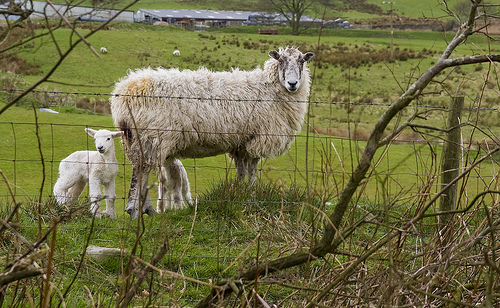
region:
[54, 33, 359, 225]
Mother and her two babies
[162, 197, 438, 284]
Weeds growing by the fence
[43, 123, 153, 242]
New baby is very white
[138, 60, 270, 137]
Mother sheep is fuzzy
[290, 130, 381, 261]
Dead stick beside the fence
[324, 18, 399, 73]
Group of bushes in the field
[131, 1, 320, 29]
Barn in the background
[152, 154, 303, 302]
Fence is made of chain link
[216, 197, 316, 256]
Dried grass by the fence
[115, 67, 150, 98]
Sheep has dirty wool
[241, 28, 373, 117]
the head of a sheep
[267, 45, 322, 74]
the eyes of a sheep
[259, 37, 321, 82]
the ears of a sheep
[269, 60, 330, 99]
the nose of a sheep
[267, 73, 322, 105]
the mouth of a sheep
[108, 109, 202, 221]
the back legs of a sheep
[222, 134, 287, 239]
the front legs of a sheep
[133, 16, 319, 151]
the body of a sheep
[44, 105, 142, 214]
a baby white sheep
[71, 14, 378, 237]
sheeps standing in the field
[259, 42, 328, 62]
the ears of a sheep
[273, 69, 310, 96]
the nose of a sheep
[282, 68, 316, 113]
the mouth of a sheep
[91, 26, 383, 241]
a sheep standing in a field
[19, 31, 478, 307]
sheep standing outside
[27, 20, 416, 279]
sheep standing in a field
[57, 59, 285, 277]
large and small sheep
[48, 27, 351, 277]
a large sheep and two baby sheep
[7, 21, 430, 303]
a field of green grass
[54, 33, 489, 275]
a field of grass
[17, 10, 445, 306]
sheep behind a fence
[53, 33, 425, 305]
sheep behind a metal fence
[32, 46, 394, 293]
sheep behind a wire fence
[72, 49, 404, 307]
sheep with metal wire fence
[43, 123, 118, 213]
white lamb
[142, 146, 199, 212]
lamb nursing from the sheep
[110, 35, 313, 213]
mother of the two lambs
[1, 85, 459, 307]
fencing in front of lambs and sheep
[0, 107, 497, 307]
dried branches around the fencing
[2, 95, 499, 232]
grass pasture sheep and lambs are in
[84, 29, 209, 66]
sheep grazing in the far distance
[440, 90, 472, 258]
wood post fencing is attached to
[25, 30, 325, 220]
mama sheep standing with her two lambs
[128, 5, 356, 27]
building on the horizon